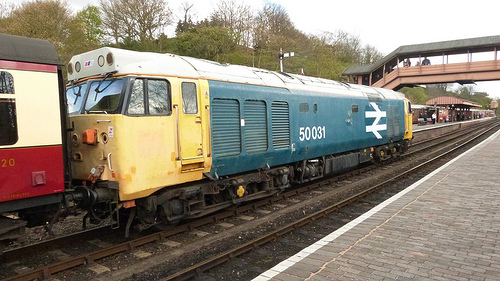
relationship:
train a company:
[64, 37, 245, 231] [363, 95, 392, 142]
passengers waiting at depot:
[452, 103, 475, 118] [417, 90, 495, 137]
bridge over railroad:
[395, 42, 494, 86] [13, 118, 500, 281]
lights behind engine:
[275, 48, 298, 58] [337, 78, 423, 152]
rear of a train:
[294, 68, 418, 161] [64, 37, 245, 231]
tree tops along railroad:
[204, 13, 304, 47] [13, 118, 500, 281]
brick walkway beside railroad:
[418, 127, 461, 143] [13, 118, 500, 281]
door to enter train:
[171, 80, 207, 167] [64, 37, 245, 231]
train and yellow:
[64, 37, 245, 231] [123, 129, 158, 173]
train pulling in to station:
[64, 37, 245, 231] [417, 90, 495, 137]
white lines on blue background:
[364, 98, 392, 142] [302, 75, 407, 151]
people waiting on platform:
[423, 109, 467, 119] [417, 93, 497, 121]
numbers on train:
[300, 124, 329, 140] [64, 37, 245, 231]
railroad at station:
[13, 118, 500, 281] [417, 90, 495, 137]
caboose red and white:
[0, 26, 74, 214] [16, 75, 56, 145]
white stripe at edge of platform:
[425, 118, 481, 131] [417, 93, 497, 121]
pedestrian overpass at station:
[378, 22, 498, 82] [417, 90, 495, 137]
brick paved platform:
[430, 130, 441, 140] [417, 93, 497, 121]